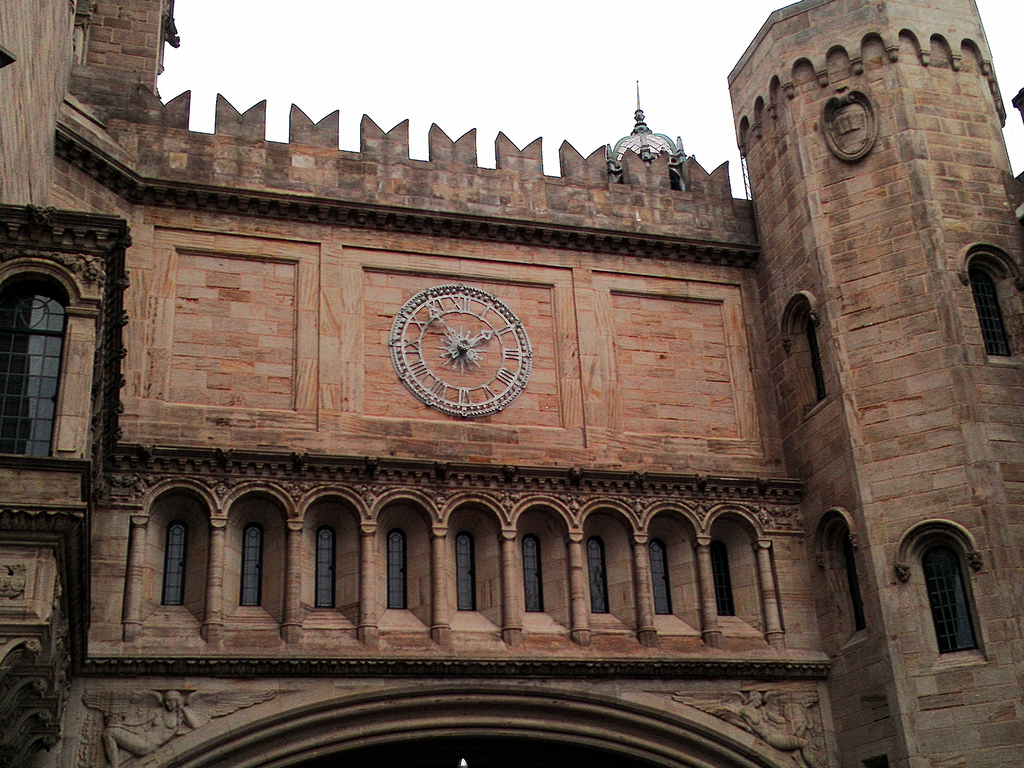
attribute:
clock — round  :
[375, 277, 546, 418]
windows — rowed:
[146, 500, 764, 630]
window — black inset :
[11, 292, 68, 450]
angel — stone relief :
[412, 281, 493, 374]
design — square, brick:
[345, 243, 588, 460]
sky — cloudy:
[188, 8, 724, 112]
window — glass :
[229, 508, 288, 606]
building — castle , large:
[4, 4, 1022, 763]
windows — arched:
[124, 475, 799, 642]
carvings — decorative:
[73, 672, 231, 744]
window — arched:
[883, 510, 1000, 671]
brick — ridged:
[124, 85, 762, 233]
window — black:
[3, 253, 83, 472]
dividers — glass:
[4, 290, 63, 450]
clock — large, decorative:
[383, 284, 533, 414]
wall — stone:
[93, 132, 830, 727]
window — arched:
[510, 491, 575, 638]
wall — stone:
[772, 13, 971, 735]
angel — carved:
[668, 681, 839, 748]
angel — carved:
[76, 677, 284, 751]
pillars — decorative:
[201, 506, 234, 630]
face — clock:
[387, 279, 530, 414]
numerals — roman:
[402, 290, 523, 401]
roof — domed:
[608, 132, 686, 174]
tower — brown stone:
[731, 11, 993, 752]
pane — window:
[923, 556, 984, 654]